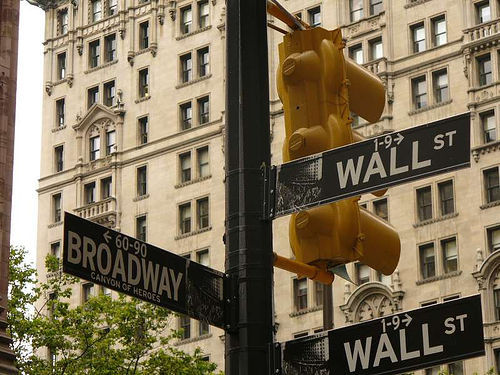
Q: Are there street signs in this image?
A: Yes, there is a street sign.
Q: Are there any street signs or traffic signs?
A: Yes, there is a street sign.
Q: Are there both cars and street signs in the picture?
A: No, there is a street sign but no cars.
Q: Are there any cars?
A: No, there are no cars.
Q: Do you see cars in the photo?
A: No, there are no cars.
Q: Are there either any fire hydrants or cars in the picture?
A: No, there are no cars or fire hydrants.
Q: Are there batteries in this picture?
A: No, there are no batteries.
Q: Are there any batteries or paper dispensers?
A: No, there are no batteries or paper dispensers.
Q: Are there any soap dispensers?
A: No, there are no soap dispensers.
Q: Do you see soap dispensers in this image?
A: No, there are no soap dispensers.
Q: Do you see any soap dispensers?
A: No, there are no soap dispensers.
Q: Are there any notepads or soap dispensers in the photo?
A: No, there are no soap dispensers or notepads.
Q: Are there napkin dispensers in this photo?
A: No, there are no napkin dispensers.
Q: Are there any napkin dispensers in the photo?
A: No, there are no napkin dispensers.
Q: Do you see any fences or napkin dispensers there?
A: No, there are no napkin dispensers or fences.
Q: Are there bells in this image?
A: No, there are no bells.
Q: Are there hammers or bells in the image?
A: No, there are no bells or hammers.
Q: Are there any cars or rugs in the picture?
A: No, there are no cars or rugs.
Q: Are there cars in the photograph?
A: No, there are no cars.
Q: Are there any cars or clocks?
A: No, there are no cars or clocks.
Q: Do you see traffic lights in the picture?
A: Yes, there is a traffic light.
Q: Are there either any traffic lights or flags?
A: Yes, there is a traffic light.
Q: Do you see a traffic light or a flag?
A: Yes, there is a traffic light.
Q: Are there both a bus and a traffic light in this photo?
A: No, there is a traffic light but no buses.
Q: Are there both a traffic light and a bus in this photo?
A: No, there is a traffic light but no buses.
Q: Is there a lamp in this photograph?
A: No, there are no lamps.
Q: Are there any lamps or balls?
A: No, there are no lamps or balls.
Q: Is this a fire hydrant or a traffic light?
A: This is a traffic light.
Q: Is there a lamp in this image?
A: No, there are no lamps.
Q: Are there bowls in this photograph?
A: No, there are no bowls.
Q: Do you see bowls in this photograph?
A: No, there are no bowls.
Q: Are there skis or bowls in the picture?
A: No, there are no bowls or skis.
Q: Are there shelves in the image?
A: No, there are no shelves.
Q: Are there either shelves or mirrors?
A: No, there are no shelves or mirrors.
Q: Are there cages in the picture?
A: No, there are no cages.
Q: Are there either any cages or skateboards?
A: No, there are no cages or skateboards.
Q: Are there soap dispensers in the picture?
A: No, there are no soap dispensers.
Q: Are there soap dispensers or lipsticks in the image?
A: No, there are no soap dispensers or lipsticks.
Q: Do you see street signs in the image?
A: Yes, there is a street sign.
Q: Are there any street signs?
A: Yes, there is a street sign.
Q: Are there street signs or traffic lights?
A: Yes, there is a street sign.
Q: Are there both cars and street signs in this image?
A: No, there is a street sign but no cars.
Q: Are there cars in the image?
A: No, there are no cars.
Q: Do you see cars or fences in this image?
A: No, there are no cars or fences.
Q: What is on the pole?
A: The street sign is on the pole.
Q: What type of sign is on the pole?
A: The sign is a street sign.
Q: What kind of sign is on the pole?
A: The sign is a street sign.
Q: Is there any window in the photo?
A: Yes, there is a window.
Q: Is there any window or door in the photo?
A: Yes, there is a window.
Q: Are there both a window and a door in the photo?
A: No, there is a window but no doors.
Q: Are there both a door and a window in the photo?
A: No, there is a window but no doors.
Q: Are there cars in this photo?
A: No, there are no cars.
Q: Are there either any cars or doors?
A: No, there are no cars or doors.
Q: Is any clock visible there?
A: No, there are no clocks.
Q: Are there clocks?
A: No, there are no clocks.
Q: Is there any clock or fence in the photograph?
A: No, there are no clocks or fences.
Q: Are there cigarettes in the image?
A: No, there are no cigarettes.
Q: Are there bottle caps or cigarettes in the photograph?
A: No, there are no cigarettes or bottle caps.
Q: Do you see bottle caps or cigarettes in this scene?
A: No, there are no cigarettes or bottle caps.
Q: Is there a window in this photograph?
A: Yes, there is a window.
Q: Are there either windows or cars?
A: Yes, there is a window.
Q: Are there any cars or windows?
A: Yes, there is a window.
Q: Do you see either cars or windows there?
A: Yes, there is a window.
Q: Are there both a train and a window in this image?
A: No, there is a window but no trains.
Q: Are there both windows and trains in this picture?
A: No, there is a window but no trains.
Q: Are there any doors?
A: No, there are no doors.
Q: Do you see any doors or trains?
A: No, there are no doors or trains.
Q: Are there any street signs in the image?
A: Yes, there is a street sign.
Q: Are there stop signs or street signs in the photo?
A: Yes, there is a street sign.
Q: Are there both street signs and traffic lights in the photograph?
A: Yes, there are both a street sign and a traffic light.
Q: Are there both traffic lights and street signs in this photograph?
A: Yes, there are both a street sign and a traffic light.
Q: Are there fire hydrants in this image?
A: No, there are no fire hydrants.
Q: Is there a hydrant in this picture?
A: No, there are no fire hydrants.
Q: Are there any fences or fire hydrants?
A: No, there are no fire hydrants or fences.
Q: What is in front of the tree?
A: The street sign is in front of the tree.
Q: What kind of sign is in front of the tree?
A: The sign is a street sign.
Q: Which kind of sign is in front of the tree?
A: The sign is a street sign.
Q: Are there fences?
A: No, there are no fences.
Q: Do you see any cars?
A: No, there are no cars.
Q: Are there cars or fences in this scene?
A: No, there are no cars or fences.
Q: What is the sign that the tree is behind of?
A: The sign is a street sign.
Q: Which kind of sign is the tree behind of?
A: The tree is behind the street sign.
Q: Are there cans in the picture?
A: No, there are no cans.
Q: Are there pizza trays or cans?
A: No, there are no cans or pizza trays.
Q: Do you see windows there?
A: Yes, there are windows.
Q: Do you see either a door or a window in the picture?
A: Yes, there are windows.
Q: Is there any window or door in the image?
A: Yes, there are windows.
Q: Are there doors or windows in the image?
A: Yes, there are windows.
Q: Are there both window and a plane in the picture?
A: No, there are windows but no airplanes.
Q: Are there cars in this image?
A: No, there are no cars.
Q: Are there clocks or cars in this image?
A: No, there are no cars or clocks.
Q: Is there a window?
A: Yes, there are windows.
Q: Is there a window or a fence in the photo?
A: Yes, there are windows.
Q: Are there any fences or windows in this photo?
A: Yes, there are windows.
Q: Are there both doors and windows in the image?
A: No, there are windows but no doors.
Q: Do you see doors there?
A: No, there are no doors.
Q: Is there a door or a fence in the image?
A: No, there are no doors or fences.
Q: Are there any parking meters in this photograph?
A: No, there are no parking meters.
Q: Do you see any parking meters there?
A: No, there are no parking meters.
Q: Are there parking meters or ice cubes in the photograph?
A: No, there are no parking meters or ice cubes.